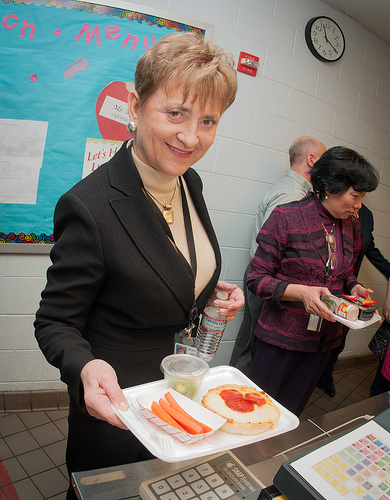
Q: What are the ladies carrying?
A: Tray with food.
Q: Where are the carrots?
A: In the cardboard on the tray.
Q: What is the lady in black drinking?
A: Water.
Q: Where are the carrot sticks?
A: On the woman's tray.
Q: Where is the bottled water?
A: In the woman's hand.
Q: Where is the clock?
A: On the wall.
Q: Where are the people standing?
A: In a lunchroom.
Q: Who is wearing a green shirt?
A: The man near the wall.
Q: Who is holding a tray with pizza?
A: The woman in a black jacket.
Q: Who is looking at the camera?
A: The woman holding a water bottle.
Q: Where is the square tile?
A: On the floor.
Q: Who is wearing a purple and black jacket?
A: The woman with dark hair.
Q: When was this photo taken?
A: Before a meal.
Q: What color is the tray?
A: White.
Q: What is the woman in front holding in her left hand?
A: A water bottle.